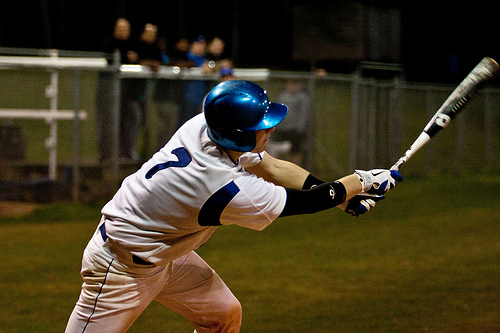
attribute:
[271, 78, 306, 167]
person — blurry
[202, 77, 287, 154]
blue helmet — Bright 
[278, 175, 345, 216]
sleeves — black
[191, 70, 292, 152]
helmet — reflecting 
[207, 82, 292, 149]
helmet — shiny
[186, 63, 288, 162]
helmet — blue, batting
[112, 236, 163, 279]
belt — black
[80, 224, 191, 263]
belt — blue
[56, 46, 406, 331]
player — having fun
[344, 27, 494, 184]
baseball bat — long, Black, white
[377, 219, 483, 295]
grass — green , Bright 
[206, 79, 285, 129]
helmet — blue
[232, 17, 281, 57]
sky — black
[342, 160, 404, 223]
gloves — white, blue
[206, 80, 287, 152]
hat — blue 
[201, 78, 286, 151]
helmet — blue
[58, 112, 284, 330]
uniform — blue, white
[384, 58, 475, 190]
bat — black, white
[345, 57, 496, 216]
bat — black, Baseball bat, in motion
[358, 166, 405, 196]
gloves — blue, white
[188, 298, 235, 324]
stain — grass 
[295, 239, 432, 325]
grass — green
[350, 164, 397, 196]
glove — blue, white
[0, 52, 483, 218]
fence — white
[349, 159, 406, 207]
gloves — batting gloves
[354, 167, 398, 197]
glove — white 